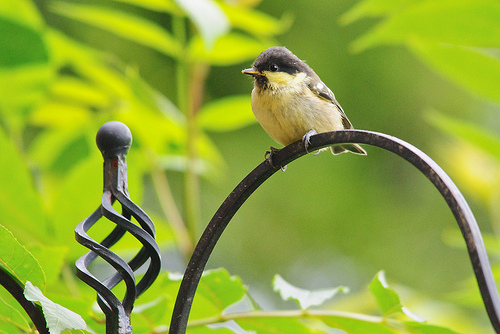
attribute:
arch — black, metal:
[166, 126, 499, 331]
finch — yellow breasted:
[238, 47, 313, 130]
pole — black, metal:
[33, 103, 170, 332]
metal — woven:
[73, 118, 161, 328]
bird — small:
[234, 43, 372, 160]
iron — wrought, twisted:
[69, 137, 168, 324]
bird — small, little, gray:
[239, 44, 369, 172]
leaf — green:
[22, 278, 94, 332]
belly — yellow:
[250, 87, 310, 140]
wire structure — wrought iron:
[165, 126, 481, 332]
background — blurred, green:
[3, 2, 483, 332]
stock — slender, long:
[172, 19, 208, 245]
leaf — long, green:
[46, 0, 183, 62]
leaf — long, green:
[186, 33, 270, 65]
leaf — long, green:
[198, 94, 257, 131]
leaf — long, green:
[215, 1, 294, 39]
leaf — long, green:
[121, 0, 187, 19]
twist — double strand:
[100, 191, 162, 299]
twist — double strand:
[94, 185, 156, 315]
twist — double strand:
[74, 197, 137, 313]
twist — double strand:
[75, 196, 126, 317]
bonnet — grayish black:
[254, 44, 302, 63]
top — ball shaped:
[93, 118, 133, 158]